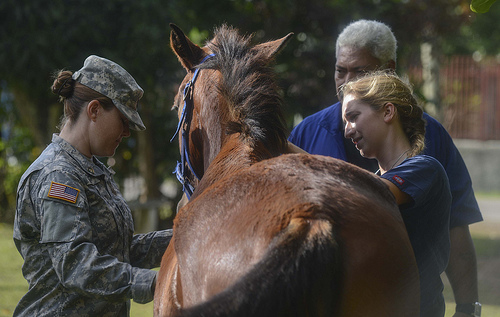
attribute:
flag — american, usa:
[43, 182, 88, 205]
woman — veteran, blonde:
[24, 63, 144, 316]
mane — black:
[224, 49, 285, 140]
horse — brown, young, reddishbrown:
[168, 34, 413, 299]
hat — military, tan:
[80, 55, 156, 129]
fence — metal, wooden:
[450, 62, 493, 142]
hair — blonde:
[359, 75, 427, 140]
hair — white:
[354, 24, 394, 50]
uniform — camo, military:
[26, 161, 131, 245]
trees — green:
[28, 14, 160, 64]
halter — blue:
[178, 121, 198, 186]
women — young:
[340, 86, 484, 300]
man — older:
[299, 14, 480, 218]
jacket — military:
[39, 147, 163, 315]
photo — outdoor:
[4, 4, 497, 315]